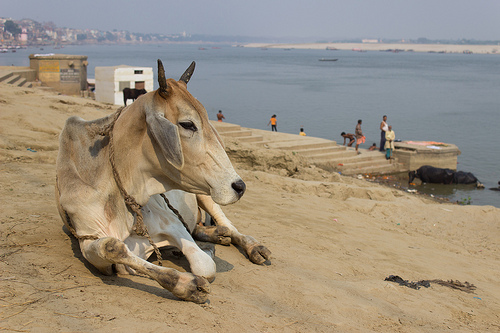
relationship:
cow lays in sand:
[52, 81, 279, 315] [281, 238, 364, 301]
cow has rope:
[52, 81, 279, 315] [100, 160, 198, 259]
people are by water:
[266, 88, 398, 160] [299, 80, 469, 102]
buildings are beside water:
[31, 41, 145, 105] [299, 80, 469, 102]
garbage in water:
[360, 173, 403, 190] [299, 80, 469, 102]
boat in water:
[317, 53, 350, 66] [299, 80, 469, 102]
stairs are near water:
[306, 138, 392, 184] [299, 80, 469, 102]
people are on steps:
[266, 88, 398, 160] [306, 138, 392, 184]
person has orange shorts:
[352, 116, 369, 151] [352, 137, 366, 145]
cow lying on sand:
[52, 81, 279, 315] [281, 238, 364, 301]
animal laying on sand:
[52, 81, 279, 315] [281, 238, 364, 301]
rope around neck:
[100, 160, 198, 259] [105, 126, 161, 226]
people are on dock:
[266, 88, 398, 160] [239, 125, 463, 170]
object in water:
[234, 35, 497, 70] [299, 80, 469, 102]